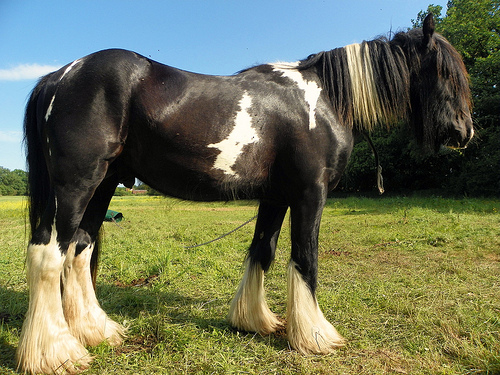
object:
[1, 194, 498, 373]
field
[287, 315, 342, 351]
hoof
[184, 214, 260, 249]
tether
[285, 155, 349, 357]
leg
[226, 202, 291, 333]
leg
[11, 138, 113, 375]
leg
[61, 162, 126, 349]
leg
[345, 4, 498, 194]
trees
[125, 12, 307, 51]
sky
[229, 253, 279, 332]
long hair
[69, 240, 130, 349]
long hair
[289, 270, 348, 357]
white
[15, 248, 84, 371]
white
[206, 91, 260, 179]
spot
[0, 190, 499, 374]
ground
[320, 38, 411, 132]
hair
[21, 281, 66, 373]
hair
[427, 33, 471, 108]
hair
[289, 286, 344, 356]
hair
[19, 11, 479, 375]
horse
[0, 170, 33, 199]
trees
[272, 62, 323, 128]
white patch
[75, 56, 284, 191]
black coat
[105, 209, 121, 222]
bucket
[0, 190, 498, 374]
grass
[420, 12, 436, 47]
ear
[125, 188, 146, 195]
house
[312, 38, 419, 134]
mane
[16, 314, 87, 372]
feet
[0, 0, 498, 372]
background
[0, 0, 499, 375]
outside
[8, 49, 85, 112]
cloud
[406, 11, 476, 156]
head